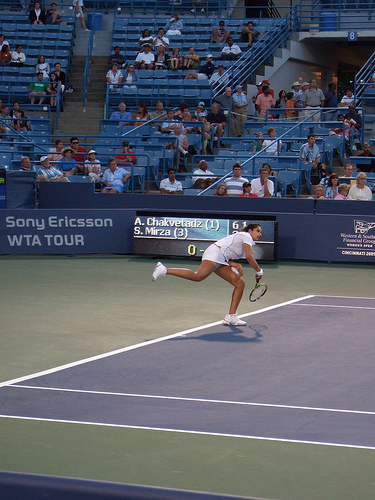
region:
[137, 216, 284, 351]
this is a player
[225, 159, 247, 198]
this is a spectator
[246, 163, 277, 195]
this is a spectator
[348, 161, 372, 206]
this is a spectator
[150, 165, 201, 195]
this is a spectator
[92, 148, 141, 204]
this is a spectator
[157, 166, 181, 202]
this is a spectator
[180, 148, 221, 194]
this is a spectator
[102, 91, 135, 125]
this is a spectator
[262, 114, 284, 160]
this is a spectator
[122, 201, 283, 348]
player is playing tennis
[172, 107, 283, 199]
the seats are blue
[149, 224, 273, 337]
Woman on a tennis court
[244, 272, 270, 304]
Tennis racket in woman's hand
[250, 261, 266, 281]
Wristband on woman's arm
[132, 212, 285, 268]
Scoreboard against the wall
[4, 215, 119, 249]
White words on wall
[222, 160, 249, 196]
Man wearing a striped shirt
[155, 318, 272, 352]
Shadow on the ground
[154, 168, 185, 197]
Man wearing a white shirt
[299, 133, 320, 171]
Man wearing a blue shirt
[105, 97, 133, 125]
Man wearing a blue shirt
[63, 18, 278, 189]
crowd sitting in the stands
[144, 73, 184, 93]
blue bleachers in stands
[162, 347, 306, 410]
purple surface of tennis court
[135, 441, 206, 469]
green surface of tennis court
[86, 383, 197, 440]
white lines drawn on tennis court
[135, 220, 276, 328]
woman playing tennis on court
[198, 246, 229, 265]
white tennis player skirt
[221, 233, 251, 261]
white top to tennis player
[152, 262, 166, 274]
white shoes of tennis player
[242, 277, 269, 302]
green and yellow tennis racket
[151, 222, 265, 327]
a lady playing tennis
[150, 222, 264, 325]
a lady swinging a tennis racket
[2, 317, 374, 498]
the tennis court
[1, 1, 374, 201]
people in the stands watching the tennis match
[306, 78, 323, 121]
a man standing up watching the match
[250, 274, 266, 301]
the tennis racket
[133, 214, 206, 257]
the billboard sign displaying the score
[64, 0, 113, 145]
stairs in the stadium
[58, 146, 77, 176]
a person in a blue shirt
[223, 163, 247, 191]
a man in a striped shirt